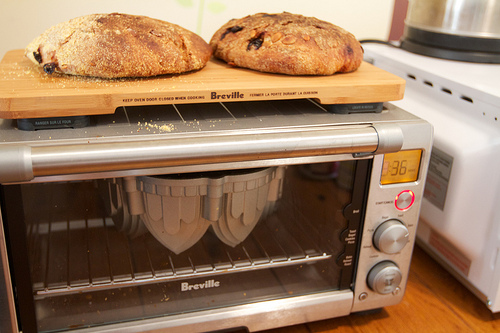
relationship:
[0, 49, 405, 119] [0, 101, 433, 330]
board on top of appliance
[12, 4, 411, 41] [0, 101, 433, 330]
wall behind appliance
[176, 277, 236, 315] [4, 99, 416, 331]
logo printed on appliance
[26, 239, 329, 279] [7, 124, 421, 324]
grill inside of appliance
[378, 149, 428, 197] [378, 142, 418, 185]
light inside of window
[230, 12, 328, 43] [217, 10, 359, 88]
raisins are on top of good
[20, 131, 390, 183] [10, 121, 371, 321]
handle attached to door